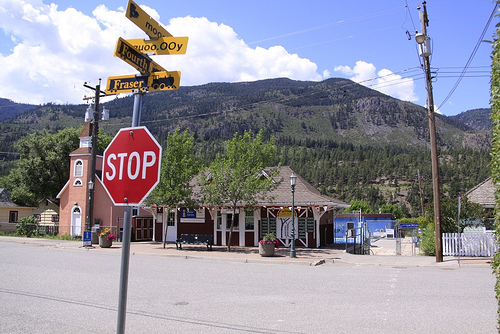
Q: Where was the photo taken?
A: It was taken at the street.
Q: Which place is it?
A: It is a street.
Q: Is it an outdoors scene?
A: Yes, it is outdoors.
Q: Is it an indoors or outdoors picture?
A: It is outdoors.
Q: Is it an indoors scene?
A: No, it is outdoors.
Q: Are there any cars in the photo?
A: No, there are no cars.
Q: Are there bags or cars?
A: No, there are no cars or bags.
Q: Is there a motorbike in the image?
A: No, there are no motorcycles.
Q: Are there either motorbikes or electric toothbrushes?
A: No, there are no motorbikes or electric toothbrushes.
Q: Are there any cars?
A: No, there are no cars.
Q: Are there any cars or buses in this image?
A: No, there are no cars or buses.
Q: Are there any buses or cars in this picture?
A: No, there are no cars or buses.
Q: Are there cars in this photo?
A: No, there are no cars.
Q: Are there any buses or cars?
A: No, there are no cars or buses.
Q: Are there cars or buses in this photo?
A: No, there are no cars or buses.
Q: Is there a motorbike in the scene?
A: No, there are no motorcycles.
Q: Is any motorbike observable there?
A: No, there are no motorcycles.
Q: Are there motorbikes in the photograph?
A: No, there are no motorbikes.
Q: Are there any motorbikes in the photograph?
A: No, there are no motorbikes.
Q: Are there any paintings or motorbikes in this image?
A: No, there are no motorbikes or paintings.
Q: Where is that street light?
A: The street light is on the side walk.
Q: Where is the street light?
A: The street light is on the side walk.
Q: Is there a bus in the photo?
A: No, there are no buses.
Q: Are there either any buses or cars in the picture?
A: No, there are no cars or buses.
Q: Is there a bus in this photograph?
A: No, there are no buses.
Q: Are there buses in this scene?
A: No, there are no buses.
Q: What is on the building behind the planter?
A: The sign is on the building.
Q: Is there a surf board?
A: No, there are no surfboards.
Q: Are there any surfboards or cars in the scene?
A: No, there are no surfboards or cars.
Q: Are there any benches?
A: Yes, there is a bench.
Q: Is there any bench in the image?
A: Yes, there is a bench.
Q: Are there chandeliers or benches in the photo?
A: Yes, there is a bench.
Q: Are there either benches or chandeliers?
A: Yes, there is a bench.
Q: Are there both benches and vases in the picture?
A: No, there is a bench but no vases.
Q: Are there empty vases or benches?
A: Yes, there is an empty bench.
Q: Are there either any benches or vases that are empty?
A: Yes, the bench is empty.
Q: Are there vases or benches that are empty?
A: Yes, the bench is empty.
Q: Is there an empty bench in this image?
A: Yes, there is an empty bench.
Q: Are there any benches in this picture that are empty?
A: Yes, there is a bench that is empty.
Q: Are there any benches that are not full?
A: Yes, there is a empty bench.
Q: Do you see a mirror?
A: No, there are no mirrors.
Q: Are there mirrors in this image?
A: No, there are no mirrors.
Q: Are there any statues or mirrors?
A: No, there are no mirrors or statues.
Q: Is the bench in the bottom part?
A: Yes, the bench is in the bottom of the image.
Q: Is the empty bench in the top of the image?
A: No, the bench is in the bottom of the image.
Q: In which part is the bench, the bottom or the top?
A: The bench is in the bottom of the image.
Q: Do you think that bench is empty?
A: Yes, the bench is empty.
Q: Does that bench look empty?
A: Yes, the bench is empty.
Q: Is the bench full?
A: No, the bench is empty.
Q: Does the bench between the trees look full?
A: No, the bench is empty.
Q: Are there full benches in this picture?
A: No, there is a bench but it is empty.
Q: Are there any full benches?
A: No, there is a bench but it is empty.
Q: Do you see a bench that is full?
A: No, there is a bench but it is empty.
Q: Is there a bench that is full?
A: No, there is a bench but it is empty.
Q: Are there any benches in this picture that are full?
A: No, there is a bench but it is empty.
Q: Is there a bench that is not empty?
A: No, there is a bench but it is empty.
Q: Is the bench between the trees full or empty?
A: The bench is empty.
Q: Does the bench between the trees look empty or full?
A: The bench is empty.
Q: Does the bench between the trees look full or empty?
A: The bench is empty.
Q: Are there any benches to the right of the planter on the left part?
A: Yes, there is a bench to the right of the planter.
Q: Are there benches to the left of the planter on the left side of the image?
A: No, the bench is to the right of the planter.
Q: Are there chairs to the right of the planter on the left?
A: No, there is a bench to the right of the planter.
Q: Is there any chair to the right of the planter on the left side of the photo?
A: No, there is a bench to the right of the planter.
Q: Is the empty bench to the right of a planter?
A: Yes, the bench is to the right of a planter.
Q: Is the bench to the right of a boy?
A: No, the bench is to the right of a planter.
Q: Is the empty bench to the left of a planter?
A: No, the bench is to the right of a planter.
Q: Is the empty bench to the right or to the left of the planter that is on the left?
A: The bench is to the right of the planter.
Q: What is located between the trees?
A: The bench is between the trees.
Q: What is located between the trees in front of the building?
A: The bench is between the trees.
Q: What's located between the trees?
A: The bench is between the trees.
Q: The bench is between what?
A: The bench is between the trees.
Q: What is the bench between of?
A: The bench is between the trees.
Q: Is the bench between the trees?
A: Yes, the bench is between the trees.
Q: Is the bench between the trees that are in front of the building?
A: Yes, the bench is between the trees.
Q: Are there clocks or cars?
A: No, there are no cars or clocks.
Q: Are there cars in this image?
A: No, there are no cars.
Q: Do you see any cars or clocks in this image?
A: No, there are no cars or clocks.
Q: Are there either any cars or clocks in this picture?
A: No, there are no cars or clocks.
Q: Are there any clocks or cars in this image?
A: No, there are no cars or clocks.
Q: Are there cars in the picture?
A: No, there are no cars.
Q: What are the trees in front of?
A: The trees are in front of the building.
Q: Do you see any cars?
A: No, there are no cars.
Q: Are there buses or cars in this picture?
A: No, there are no cars or buses.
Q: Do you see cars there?
A: No, there are no cars.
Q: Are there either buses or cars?
A: No, there are no cars or buses.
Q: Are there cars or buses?
A: No, there are no cars or buses.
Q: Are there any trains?
A: Yes, there is a train.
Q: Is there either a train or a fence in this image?
A: Yes, there is a train.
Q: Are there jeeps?
A: No, there are no jeeps.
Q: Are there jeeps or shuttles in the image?
A: No, there are no jeeps or shuttles.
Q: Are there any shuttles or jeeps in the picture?
A: No, there are no jeeps or shuttles.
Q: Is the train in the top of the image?
A: Yes, the train is in the top of the image.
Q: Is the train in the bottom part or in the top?
A: The train is in the top of the image.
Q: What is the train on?
A: The train is on the sign.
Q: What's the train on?
A: The train is on the sign.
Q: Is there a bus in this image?
A: No, there are no buses.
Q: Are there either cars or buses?
A: No, there are no buses or cars.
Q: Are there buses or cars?
A: No, there are no buses or cars.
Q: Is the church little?
A: Yes, the church is little.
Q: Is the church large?
A: No, the church is little.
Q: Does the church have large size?
A: No, the church is little.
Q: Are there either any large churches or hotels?
A: No, there is a church but it is little.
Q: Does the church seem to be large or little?
A: The church is little.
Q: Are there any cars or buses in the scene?
A: No, there are no cars or buses.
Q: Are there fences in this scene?
A: Yes, there is a fence.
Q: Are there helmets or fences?
A: Yes, there is a fence.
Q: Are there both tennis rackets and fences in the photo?
A: No, there is a fence but no rackets.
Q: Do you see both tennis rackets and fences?
A: No, there is a fence but no rackets.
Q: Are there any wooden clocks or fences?
A: Yes, there is a wood fence.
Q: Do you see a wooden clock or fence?
A: Yes, there is a wood fence.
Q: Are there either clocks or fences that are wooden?
A: Yes, the fence is wooden.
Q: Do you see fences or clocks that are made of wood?
A: Yes, the fence is made of wood.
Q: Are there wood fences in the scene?
A: Yes, there is a wood fence.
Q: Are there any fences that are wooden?
A: Yes, there is a fence that is wooden.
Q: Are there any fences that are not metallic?
A: Yes, there is a wooden fence.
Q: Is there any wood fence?
A: Yes, there is a fence that is made of wood.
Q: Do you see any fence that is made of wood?
A: Yes, there is a fence that is made of wood.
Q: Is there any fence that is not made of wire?
A: Yes, there is a fence that is made of wood.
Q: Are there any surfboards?
A: No, there are no surfboards.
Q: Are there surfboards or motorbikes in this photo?
A: No, there are no surfboards or motorbikes.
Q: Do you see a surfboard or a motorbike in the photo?
A: No, there are no surfboards or motorcycles.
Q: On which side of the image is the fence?
A: The fence is on the right of the image.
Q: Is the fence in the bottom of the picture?
A: Yes, the fence is in the bottom of the image.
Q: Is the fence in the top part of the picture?
A: No, the fence is in the bottom of the image.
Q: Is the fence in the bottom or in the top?
A: The fence is in the bottom of the image.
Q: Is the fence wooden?
A: Yes, the fence is wooden.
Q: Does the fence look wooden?
A: Yes, the fence is wooden.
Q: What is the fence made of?
A: The fence is made of wood.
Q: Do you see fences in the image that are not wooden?
A: No, there is a fence but it is wooden.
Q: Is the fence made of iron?
A: No, the fence is made of wood.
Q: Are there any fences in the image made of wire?
A: No, there is a fence but it is made of wood.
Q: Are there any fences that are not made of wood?
A: No, there is a fence but it is made of wood.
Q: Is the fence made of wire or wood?
A: The fence is made of wood.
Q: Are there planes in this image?
A: No, there are no planes.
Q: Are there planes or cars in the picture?
A: No, there are no planes or cars.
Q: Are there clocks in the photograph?
A: No, there are no clocks.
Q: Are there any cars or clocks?
A: No, there are no clocks or cars.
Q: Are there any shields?
A: No, there are no shields.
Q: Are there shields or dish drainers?
A: No, there are no shields or dish drainers.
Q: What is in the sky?
A: The clouds are in the sky.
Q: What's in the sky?
A: The clouds are in the sky.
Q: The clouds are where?
A: The clouds are in the sky.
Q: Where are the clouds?
A: The clouds are in the sky.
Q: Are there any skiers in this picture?
A: No, there are no skiers.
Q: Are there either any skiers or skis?
A: No, there are no skiers or skis.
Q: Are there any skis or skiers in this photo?
A: No, there are no skiers or skis.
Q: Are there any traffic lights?
A: No, there are no traffic lights.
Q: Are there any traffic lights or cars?
A: No, there are no traffic lights or cars.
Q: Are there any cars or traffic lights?
A: No, there are no traffic lights or cars.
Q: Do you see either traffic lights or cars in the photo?
A: No, there are no traffic lights or cars.